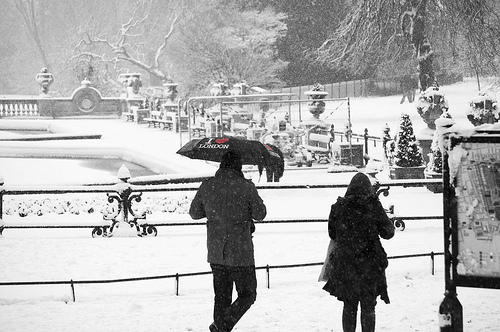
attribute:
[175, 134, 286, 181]
umbrella — black, red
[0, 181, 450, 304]
rails — black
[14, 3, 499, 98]
trees — snowy, bare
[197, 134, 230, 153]
words — white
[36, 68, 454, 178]
sculpture — snowy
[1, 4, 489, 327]
snow — white, bright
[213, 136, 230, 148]
heart — red, colorful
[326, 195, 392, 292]
jacket — dark, black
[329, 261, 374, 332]
pants — black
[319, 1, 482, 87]
tree — snowy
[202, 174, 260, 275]
clothes — black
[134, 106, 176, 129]
bench — snowy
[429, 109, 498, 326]
sign — snowy